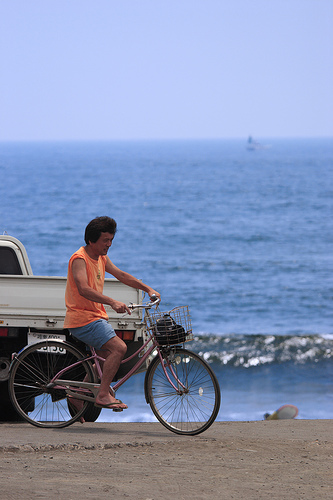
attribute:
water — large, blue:
[201, 185, 248, 255]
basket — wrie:
[138, 305, 189, 342]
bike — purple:
[0, 308, 220, 432]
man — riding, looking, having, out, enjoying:
[55, 207, 157, 427]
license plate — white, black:
[14, 327, 65, 355]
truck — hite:
[53, 295, 123, 345]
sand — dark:
[241, 430, 261, 442]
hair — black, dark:
[81, 216, 103, 232]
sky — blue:
[197, 3, 233, 39]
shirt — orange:
[67, 297, 89, 318]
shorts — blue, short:
[89, 330, 108, 342]